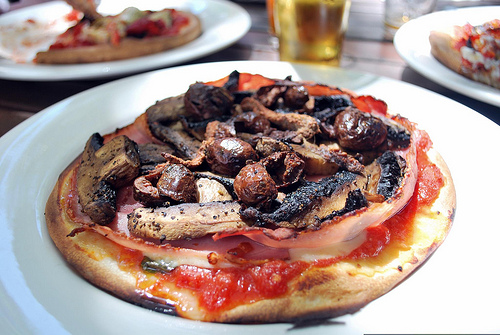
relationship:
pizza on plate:
[60, 28, 452, 325] [1, 58, 499, 333]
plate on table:
[1, 58, 499, 333] [1, 0, 498, 135]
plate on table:
[393, 5, 497, 105] [1, 0, 498, 135]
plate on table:
[0, 0, 252, 82] [1, 0, 498, 135]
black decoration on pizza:
[288, 189, 321, 213] [40, 67, 459, 324]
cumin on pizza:
[134, 201, 240, 224] [40, 67, 459, 324]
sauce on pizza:
[178, 257, 314, 309] [40, 67, 459, 324]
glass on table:
[266, 0, 359, 70] [5, 3, 495, 110]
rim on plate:
[3, 58, 223, 78] [1, 58, 499, 333]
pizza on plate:
[444, 18, 499, 83] [393, 5, 497, 105]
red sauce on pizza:
[175, 207, 429, 310] [40, 67, 459, 324]